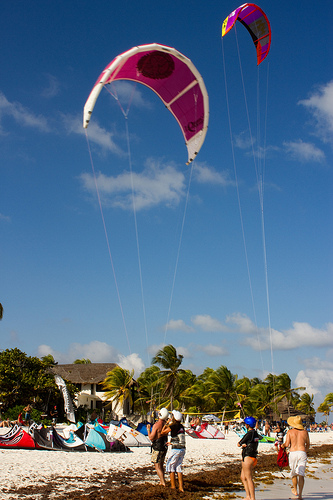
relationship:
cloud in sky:
[66, 106, 127, 156] [1, 0, 332, 422]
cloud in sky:
[77, 157, 185, 213] [1, 0, 332, 422]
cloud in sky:
[196, 162, 230, 189] [1, 0, 332, 422]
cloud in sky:
[284, 139, 322, 162] [1, 0, 332, 422]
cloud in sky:
[298, 79, 332, 140] [1, 0, 332, 422]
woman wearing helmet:
[236, 414, 261, 499] [244, 413, 255, 428]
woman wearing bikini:
[236, 414, 261, 499] [249, 454, 261, 468]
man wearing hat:
[278, 412, 313, 499] [284, 410, 315, 431]